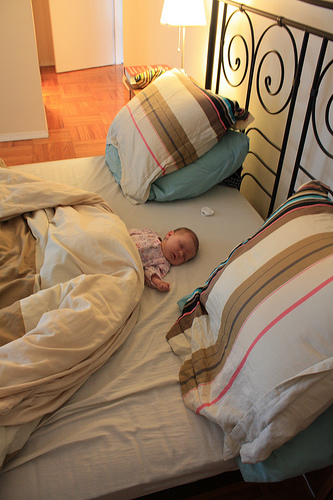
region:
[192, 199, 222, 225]
a white baby teether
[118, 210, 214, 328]
a girl baby laying in bed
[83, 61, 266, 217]
a pile of pillows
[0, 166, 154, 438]
a brown and white comforter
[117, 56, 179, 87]
a large hard cover book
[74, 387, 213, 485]
a white cotton sheet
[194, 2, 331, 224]
a black metal bed frame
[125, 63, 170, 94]
a colorful bag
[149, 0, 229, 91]
a glowing white lamp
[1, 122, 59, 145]
a clean white baseboard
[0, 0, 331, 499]
bedroom with sleeping baby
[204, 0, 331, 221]
wrought iron bed headboard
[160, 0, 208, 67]
brass table lamp turned on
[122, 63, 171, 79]
large red hardcover book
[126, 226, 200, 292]
sleeping baby in onesie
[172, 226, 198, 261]
fine dark brown hair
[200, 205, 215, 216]
plastic white pacifier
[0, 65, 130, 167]
medium brown parquet wood floor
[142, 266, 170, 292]
baby's tiny left arm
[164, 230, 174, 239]
baby's tiny right ear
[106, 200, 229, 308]
Baby laying on the bed sleeping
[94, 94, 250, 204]
Two pillows stacked on top of each other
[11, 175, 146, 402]
Crumpled up comforter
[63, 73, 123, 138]
Woodfloor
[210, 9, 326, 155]
Curved metal headboard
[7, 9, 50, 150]
Beige and white colored wall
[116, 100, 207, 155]
Striped design pillow case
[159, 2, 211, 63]
Lamp with light on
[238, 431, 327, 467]
Blue pillow on bottom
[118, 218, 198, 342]
Baby girl wearing pink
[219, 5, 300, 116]
Round curls in metal headboard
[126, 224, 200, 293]
A baby sleeping in a large bed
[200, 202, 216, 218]
Baby's pacifier on the bed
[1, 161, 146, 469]
Tan and brown blanket covers baby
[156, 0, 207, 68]
Lamp with a white shade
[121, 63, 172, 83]
A large book on the night stand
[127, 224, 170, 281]
Pink infant pajamas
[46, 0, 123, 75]
White, open door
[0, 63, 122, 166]
Wooden flooring tiles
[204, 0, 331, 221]
Wrought iron headboard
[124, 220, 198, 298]
Baby sleeping in bed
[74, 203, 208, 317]
Baby half covered by blanket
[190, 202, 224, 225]
White pacifier on bed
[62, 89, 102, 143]
Brown wooden floor tiles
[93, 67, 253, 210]
Two pillow on baby's right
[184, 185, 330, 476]
Two pillows on baby's left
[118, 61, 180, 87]
Red book on nightstand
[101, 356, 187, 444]
Wrinkles in white sheet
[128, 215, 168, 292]
Pink sleeper on baby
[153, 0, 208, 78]
Lamp on side of bed